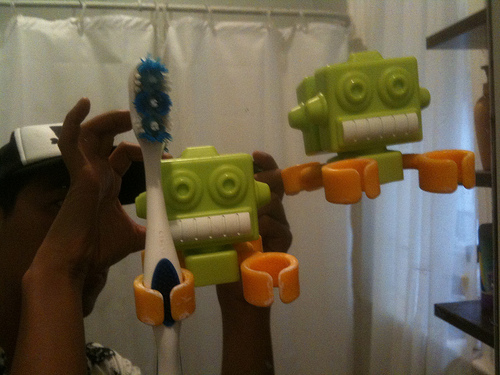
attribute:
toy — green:
[148, 145, 273, 311]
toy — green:
[116, 128, 262, 310]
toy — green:
[129, 137, 269, 305]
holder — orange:
[126, 259, 198, 327]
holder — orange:
[235, 237, 305, 316]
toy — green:
[283, 40, 433, 196]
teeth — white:
[336, 114, 415, 146]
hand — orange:
[313, 145, 386, 217]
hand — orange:
[414, 141, 487, 209]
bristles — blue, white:
[124, 60, 173, 148]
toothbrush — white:
[118, 43, 193, 302]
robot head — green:
[126, 152, 266, 269]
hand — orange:
[127, 262, 207, 332]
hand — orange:
[243, 245, 306, 296]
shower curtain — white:
[0, 0, 497, 370]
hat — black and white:
[2, 118, 145, 199]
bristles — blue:
[133, 55, 175, 145]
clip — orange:
[130, 260, 200, 327]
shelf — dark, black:
[425, 0, 498, 373]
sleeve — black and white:
[78, 333, 145, 373]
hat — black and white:
[1, 120, 149, 204]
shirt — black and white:
[81, 339, 148, 373]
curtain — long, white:
[344, 0, 496, 373]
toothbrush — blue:
[127, 55, 189, 373]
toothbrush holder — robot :
[275, 49, 481, 219]